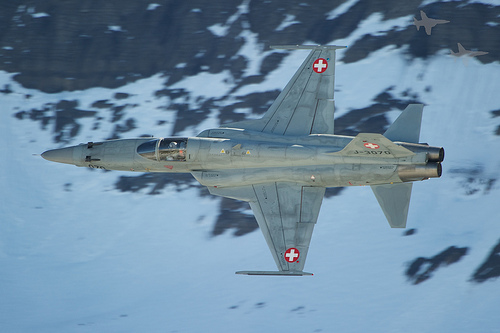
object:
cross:
[311, 56, 329, 74]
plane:
[40, 45, 444, 278]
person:
[165, 140, 185, 160]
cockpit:
[137, 137, 188, 164]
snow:
[0, 3, 500, 332]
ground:
[0, 1, 500, 332]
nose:
[38, 144, 74, 167]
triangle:
[219, 147, 226, 154]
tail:
[336, 102, 443, 229]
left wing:
[232, 163, 329, 278]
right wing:
[252, 41, 348, 135]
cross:
[364, 142, 380, 151]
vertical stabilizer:
[335, 131, 416, 158]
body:
[45, 129, 442, 191]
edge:
[236, 268, 314, 279]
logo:
[362, 137, 379, 154]